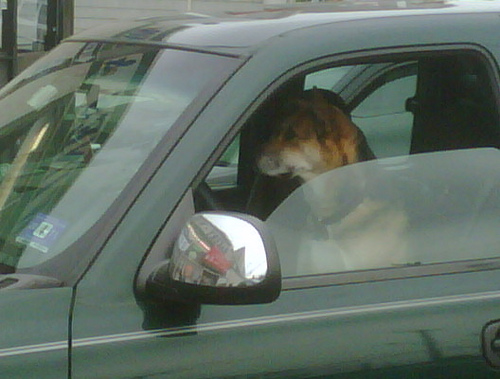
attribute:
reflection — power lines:
[188, 230, 237, 283]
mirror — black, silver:
[157, 203, 275, 312]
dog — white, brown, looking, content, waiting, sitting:
[258, 94, 403, 257]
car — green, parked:
[0, 8, 498, 378]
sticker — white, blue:
[7, 206, 72, 259]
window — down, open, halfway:
[265, 144, 498, 274]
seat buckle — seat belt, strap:
[397, 83, 438, 115]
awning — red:
[204, 243, 231, 276]